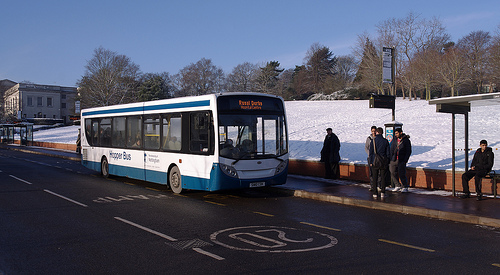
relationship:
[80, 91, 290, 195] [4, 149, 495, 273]
bus on road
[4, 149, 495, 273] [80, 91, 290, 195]
road has bus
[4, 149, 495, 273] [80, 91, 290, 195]
road with bus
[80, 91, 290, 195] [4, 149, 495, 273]
bus in road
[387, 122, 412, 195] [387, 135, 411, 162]
man wearing jacket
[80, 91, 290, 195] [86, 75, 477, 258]
bus on road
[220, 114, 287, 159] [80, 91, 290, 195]
glass on bus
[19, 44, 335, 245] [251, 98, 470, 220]
bus with passengers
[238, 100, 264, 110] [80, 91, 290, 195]
display on bus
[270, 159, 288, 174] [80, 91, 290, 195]
light on bus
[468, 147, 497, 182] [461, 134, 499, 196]
black jacket on man